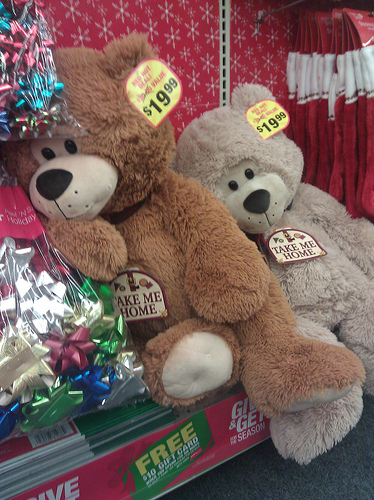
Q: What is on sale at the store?
A: Two brown teddy bears.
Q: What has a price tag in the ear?
A: A beige teddy bear that is for sale.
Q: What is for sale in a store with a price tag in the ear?
A: A brown teddy bear.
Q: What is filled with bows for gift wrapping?
A: A plastic bag.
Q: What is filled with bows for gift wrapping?
A: The corner of a plastic bag.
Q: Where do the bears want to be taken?
A: Home.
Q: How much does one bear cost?
A: 19.99.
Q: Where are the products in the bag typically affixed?
A: Gifts.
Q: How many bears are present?
A: 2.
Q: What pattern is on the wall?
A: Snowflakes.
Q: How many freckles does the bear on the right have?
A: 5.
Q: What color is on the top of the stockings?
A: White.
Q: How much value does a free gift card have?
A: $10.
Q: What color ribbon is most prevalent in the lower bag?
A: Silver.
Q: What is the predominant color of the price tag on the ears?
A: Yellow.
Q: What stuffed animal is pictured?
A: Teddy bear.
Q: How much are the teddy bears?
A: 19.99.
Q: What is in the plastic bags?
A: Bows.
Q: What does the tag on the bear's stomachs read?
A: Take me home.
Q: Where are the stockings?
A: Next to the bears.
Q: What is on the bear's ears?
A: Price tags.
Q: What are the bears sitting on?
A: Shelf.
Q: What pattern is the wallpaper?
A: Snowflakes.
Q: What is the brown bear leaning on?
A: Bows.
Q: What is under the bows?
A: Tissue paper.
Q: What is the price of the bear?
A: 19.99.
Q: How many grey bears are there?
A: One.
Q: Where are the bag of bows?
A: On the left.